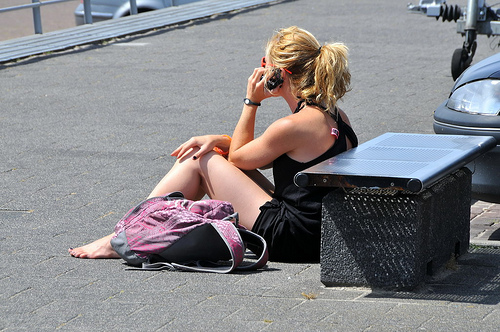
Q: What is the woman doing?
A: Talking on the phone.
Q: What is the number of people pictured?
A: One.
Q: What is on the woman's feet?
A: Nothing.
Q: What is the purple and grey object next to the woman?
A: A backpack.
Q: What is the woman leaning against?
A: A grey bench.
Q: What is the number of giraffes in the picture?
A: Zero.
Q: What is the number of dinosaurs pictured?
A: Zero.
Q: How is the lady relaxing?
A: By sitting down.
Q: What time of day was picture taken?
A: In the daytime.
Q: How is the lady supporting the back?
A: Resting against the bench.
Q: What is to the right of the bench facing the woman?
A: A car.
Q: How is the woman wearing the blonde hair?
A: In a ponytail.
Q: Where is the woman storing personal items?
A: In a backpack.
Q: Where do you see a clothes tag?
A: On the back of the woman's shirt.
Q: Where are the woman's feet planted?
A: On the concrete.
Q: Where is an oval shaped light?
A: On the car.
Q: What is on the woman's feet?
A: Nothing.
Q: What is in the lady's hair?
A: A ponytail.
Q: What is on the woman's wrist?
A: Watch.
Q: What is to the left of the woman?
A: Pink backpack.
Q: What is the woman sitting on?
A: A cement walkway.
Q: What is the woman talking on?
A: Cell phone.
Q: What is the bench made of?
A: Concrete and metal.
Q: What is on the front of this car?
A: A bumper.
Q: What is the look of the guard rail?
A: It looks gray.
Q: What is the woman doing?
A: Talking on the phone.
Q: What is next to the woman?
A: A backpack.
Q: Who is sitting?
A: The woman.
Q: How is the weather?
A: Sunny.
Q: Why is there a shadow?
A: The sun is out.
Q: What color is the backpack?
A: Purple.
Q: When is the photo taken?
A: Daytime.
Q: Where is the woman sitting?
A: On the ground.